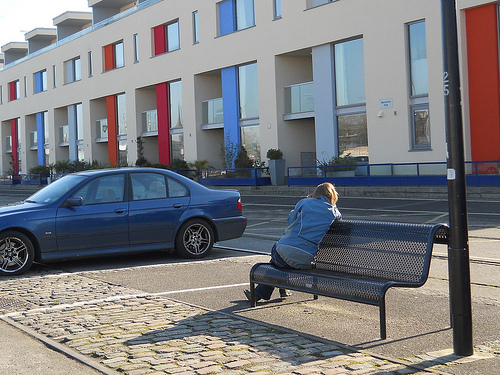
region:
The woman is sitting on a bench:
[239, 172, 355, 311]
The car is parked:
[6, 137, 306, 290]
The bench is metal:
[333, 228, 436, 323]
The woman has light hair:
[288, 173, 361, 209]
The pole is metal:
[438, 59, 483, 365]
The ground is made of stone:
[19, 283, 221, 371]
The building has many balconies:
[28, 57, 405, 205]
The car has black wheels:
[159, 220, 245, 267]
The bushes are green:
[122, 141, 352, 194]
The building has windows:
[323, 101, 496, 161]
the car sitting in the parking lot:
[0, 166, 242, 267]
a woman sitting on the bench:
[267, 182, 339, 271]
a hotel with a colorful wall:
[1, 2, 497, 197]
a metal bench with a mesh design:
[246, 217, 449, 339]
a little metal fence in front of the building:
[195, 160, 498, 194]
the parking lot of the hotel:
[2, 185, 495, 373]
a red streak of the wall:
[151, 83, 172, 166]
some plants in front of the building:
[33, 157, 191, 174]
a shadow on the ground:
[125, 295, 356, 374]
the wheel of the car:
[178, 216, 215, 258]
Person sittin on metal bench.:
[242, 175, 349, 307]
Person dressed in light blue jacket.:
[274, 193, 337, 273]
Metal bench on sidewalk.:
[327, 213, 444, 352]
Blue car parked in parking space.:
[3, 158, 247, 279]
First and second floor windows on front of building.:
[153, 3, 197, 171]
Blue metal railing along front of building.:
[281, 156, 446, 186]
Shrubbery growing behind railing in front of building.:
[20, 137, 280, 169]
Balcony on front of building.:
[282, 58, 322, 125]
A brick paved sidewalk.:
[42, 292, 256, 371]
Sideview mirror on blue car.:
[60, 188, 87, 211]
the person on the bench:
[251, 171, 336, 311]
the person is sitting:
[228, 167, 344, 322]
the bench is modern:
[248, 215, 447, 345]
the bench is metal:
[246, 220, 457, 337]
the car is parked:
[0, 156, 241, 273]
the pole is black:
[430, 5, 495, 360]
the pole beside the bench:
[438, 0, 490, 358]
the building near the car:
[1, 0, 498, 197]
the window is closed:
[333, 40, 373, 111]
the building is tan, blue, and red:
[23, 0, 495, 176]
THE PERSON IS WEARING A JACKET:
[272, 189, 337, 262]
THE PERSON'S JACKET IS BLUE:
[280, 191, 351, 257]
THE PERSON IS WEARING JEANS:
[250, 240, 296, 303]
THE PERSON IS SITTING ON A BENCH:
[244, 174, 458, 344]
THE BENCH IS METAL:
[243, 212, 462, 341]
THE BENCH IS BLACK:
[243, 205, 460, 344]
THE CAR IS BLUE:
[0, 157, 250, 264]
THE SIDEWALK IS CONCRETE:
[0, 187, 499, 373]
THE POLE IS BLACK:
[440, 1, 477, 355]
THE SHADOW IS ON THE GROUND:
[103, 293, 365, 373]